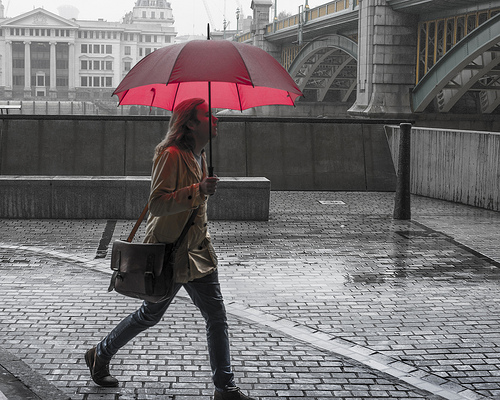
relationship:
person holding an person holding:
[165, 10, 226, 223] [81, 23, 305, 400]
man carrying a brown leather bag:
[113, 129, 216, 287] [100, 233, 196, 284]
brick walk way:
[280, 206, 341, 281] [27, 214, 101, 284]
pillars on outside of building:
[9, 36, 84, 97] [9, 8, 152, 100]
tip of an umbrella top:
[190, 27, 219, 37] [190, 10, 223, 40]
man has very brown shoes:
[80, 333, 235, 399] [58, 331, 302, 395]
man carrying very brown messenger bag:
[113, 129, 216, 287] [100, 233, 196, 284]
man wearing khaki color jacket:
[113, 129, 216, 287] [143, 127, 230, 272]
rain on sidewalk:
[320, 212, 468, 328] [283, 180, 427, 377]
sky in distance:
[0, 0, 315, 45] [71, 3, 273, 27]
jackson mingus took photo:
[369, 309, 493, 399] [17, 9, 494, 358]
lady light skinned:
[127, 3, 346, 400] [171, 103, 224, 145]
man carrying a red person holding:
[113, 129, 216, 287] [81, 23, 305, 400]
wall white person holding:
[9, 8, 152, 100] [81, 23, 305, 400]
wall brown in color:
[16, 114, 365, 195] [79, 23, 383, 135]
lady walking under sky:
[84, 96, 264, 400] [52, 4, 266, 45]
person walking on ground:
[80, 3, 251, 368] [0, 190, 500, 399]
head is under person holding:
[141, 87, 231, 171] [81, 23, 305, 400]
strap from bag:
[109, 196, 214, 244] [100, 233, 196, 284]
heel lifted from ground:
[69, 338, 143, 398] [43, 303, 78, 375]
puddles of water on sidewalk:
[278, 194, 455, 286] [283, 180, 427, 377]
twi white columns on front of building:
[10, 19, 101, 104] [9, 8, 152, 100]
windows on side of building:
[17, 31, 135, 95] [9, 8, 152, 100]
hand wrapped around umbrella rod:
[204, 152, 224, 206] [193, 70, 227, 204]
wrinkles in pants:
[98, 309, 302, 381] [83, 261, 260, 368]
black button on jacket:
[178, 177, 209, 217] [143, 127, 230, 272]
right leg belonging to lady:
[93, 276, 182, 365] [84, 96, 264, 400]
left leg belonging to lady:
[182, 265, 240, 391] [84, 96, 264, 400]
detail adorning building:
[7, 26, 27, 36] [9, 8, 152, 100]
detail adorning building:
[27, 27, 53, 36] [9, 8, 152, 100]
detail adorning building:
[51, 28, 71, 38] [9, 8, 152, 100]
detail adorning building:
[7, 11, 73, 25] [9, 8, 152, 100]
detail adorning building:
[78, 29, 118, 40] [9, 8, 152, 100]